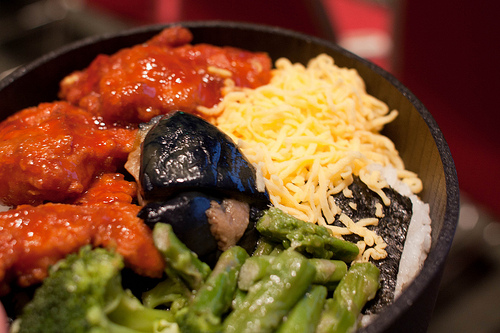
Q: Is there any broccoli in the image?
A: Yes, there is broccoli.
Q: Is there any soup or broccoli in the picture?
A: Yes, there is broccoli.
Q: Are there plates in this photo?
A: No, there are no plates.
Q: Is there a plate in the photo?
A: No, there are no plates.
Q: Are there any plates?
A: No, there are no plates.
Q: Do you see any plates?
A: No, there are no plates.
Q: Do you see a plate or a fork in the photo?
A: No, there are no plates or forks.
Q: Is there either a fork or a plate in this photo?
A: No, there are no plates or forks.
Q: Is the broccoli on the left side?
A: Yes, the broccoli is on the left of the image.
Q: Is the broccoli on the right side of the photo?
A: No, the broccoli is on the left of the image.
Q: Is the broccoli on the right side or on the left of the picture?
A: The broccoli is on the left of the image.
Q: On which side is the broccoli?
A: The broccoli is on the left of the image.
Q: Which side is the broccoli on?
A: The broccoli is on the left of the image.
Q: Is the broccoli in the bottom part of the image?
A: Yes, the broccoli is in the bottom of the image.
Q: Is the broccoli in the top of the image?
A: No, the broccoli is in the bottom of the image.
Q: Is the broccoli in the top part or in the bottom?
A: The broccoli is in the bottom of the image.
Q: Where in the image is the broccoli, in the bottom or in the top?
A: The broccoli is in the bottom of the image.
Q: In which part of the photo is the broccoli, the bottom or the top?
A: The broccoli is in the bottom of the image.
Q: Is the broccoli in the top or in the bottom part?
A: The broccoli is in the bottom of the image.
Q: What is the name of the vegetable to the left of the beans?
A: The vegetable is broccoli.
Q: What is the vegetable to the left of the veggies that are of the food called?
A: The vegetable is broccoli.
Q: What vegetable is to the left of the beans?
A: The vegetable is broccoli.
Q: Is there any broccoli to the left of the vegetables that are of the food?
A: Yes, there is broccoli to the left of the beans.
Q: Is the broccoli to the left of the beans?
A: Yes, the broccoli is to the left of the beans.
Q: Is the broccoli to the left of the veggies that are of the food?
A: Yes, the broccoli is to the left of the beans.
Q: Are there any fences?
A: No, there are no fences.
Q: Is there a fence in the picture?
A: No, there are no fences.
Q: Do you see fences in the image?
A: No, there are no fences.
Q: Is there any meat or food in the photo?
A: Yes, there is food.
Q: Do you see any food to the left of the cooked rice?
A: Yes, there is food to the left of the rice.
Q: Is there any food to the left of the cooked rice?
A: Yes, there is food to the left of the rice.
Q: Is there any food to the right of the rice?
A: No, the food is to the left of the rice.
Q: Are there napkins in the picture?
A: No, there are no napkins.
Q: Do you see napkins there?
A: No, there are no napkins.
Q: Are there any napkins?
A: No, there are no napkins.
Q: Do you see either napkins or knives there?
A: No, there are no napkins or knives.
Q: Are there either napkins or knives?
A: No, there are no napkins or knives.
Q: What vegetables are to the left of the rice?
A: The vegetables are beans.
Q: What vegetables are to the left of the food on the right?
A: The vegetables are beans.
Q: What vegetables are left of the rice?
A: The vegetables are beans.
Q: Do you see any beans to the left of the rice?
A: Yes, there are beans to the left of the rice.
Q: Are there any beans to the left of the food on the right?
A: Yes, there are beans to the left of the rice.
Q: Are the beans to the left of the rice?
A: Yes, the beans are to the left of the rice.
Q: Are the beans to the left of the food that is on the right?
A: Yes, the beans are to the left of the rice.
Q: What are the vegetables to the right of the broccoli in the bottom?
A: The vegetables are beans.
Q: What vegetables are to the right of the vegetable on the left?
A: The vegetables are beans.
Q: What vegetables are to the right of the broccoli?
A: The vegetables are beans.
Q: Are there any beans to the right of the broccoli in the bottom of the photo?
A: Yes, there are beans to the right of the broccoli.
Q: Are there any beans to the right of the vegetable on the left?
A: Yes, there are beans to the right of the broccoli.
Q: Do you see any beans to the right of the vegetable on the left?
A: Yes, there are beans to the right of the broccoli.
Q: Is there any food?
A: Yes, there is food.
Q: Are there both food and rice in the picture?
A: Yes, there are both food and rice.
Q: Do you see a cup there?
A: No, there are no cups.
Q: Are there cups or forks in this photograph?
A: No, there are no cups or forks.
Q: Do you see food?
A: Yes, there is food.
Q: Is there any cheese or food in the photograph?
A: Yes, there is food.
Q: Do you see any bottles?
A: No, there are no bottles.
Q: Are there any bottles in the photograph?
A: No, there are no bottles.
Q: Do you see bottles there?
A: No, there are no bottles.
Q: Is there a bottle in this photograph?
A: No, there are no bottles.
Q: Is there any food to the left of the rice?
A: Yes, there is food to the left of the rice.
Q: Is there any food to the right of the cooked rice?
A: No, the food is to the left of the rice.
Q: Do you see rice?
A: Yes, there is rice.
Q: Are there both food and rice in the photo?
A: Yes, there are both rice and food.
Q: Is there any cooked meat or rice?
A: Yes, there is cooked rice.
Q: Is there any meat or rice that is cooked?
A: Yes, the rice is cooked.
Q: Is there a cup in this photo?
A: No, there are no cups.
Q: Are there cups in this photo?
A: No, there are no cups.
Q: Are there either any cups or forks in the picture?
A: No, there are no cups or forks.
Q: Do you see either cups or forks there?
A: No, there are no cups or forks.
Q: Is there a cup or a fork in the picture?
A: No, there are no cups or forks.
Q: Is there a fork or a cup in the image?
A: No, there are no cups or forks.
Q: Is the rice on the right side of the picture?
A: Yes, the rice is on the right of the image.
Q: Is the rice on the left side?
A: No, the rice is on the right of the image.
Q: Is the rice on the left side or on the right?
A: The rice is on the right of the image.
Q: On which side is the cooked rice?
A: The rice is on the right of the image.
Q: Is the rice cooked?
A: Yes, the rice is cooked.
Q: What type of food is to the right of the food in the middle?
A: The food is rice.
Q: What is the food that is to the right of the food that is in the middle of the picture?
A: The food is rice.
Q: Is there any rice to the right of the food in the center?
A: Yes, there is rice to the right of the food.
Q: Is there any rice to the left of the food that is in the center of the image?
A: No, the rice is to the right of the food.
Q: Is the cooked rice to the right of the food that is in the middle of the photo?
A: Yes, the rice is to the right of the food.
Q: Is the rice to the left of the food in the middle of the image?
A: No, the rice is to the right of the food.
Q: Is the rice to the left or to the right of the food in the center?
A: The rice is to the right of the food.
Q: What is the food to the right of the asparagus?
A: The food is rice.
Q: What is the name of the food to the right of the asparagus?
A: The food is rice.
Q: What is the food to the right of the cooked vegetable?
A: The food is rice.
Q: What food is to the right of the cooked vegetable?
A: The food is rice.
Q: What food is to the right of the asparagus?
A: The food is rice.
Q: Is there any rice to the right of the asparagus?
A: Yes, there is rice to the right of the asparagus.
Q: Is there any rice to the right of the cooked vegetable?
A: Yes, there is rice to the right of the asparagus.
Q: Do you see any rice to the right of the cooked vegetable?
A: Yes, there is rice to the right of the asparagus.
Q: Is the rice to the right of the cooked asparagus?
A: Yes, the rice is to the right of the asparagus.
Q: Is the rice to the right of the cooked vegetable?
A: Yes, the rice is to the right of the asparagus.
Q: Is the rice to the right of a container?
A: No, the rice is to the right of the asparagus.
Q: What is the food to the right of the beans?
A: The food is rice.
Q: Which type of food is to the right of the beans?
A: The food is rice.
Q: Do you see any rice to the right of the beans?
A: Yes, there is rice to the right of the beans.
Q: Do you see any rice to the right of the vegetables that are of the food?
A: Yes, there is rice to the right of the beans.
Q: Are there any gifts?
A: No, there are no gifts.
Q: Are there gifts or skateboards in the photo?
A: No, there are no gifts or skateboards.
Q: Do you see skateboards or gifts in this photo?
A: No, there are no gifts or skateboards.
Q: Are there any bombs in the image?
A: No, there are no bombs.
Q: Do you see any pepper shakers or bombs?
A: No, there are no bombs or pepper shakers.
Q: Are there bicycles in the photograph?
A: No, there are no bicycles.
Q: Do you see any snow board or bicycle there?
A: No, there are no bicycles or snowboards.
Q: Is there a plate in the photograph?
A: No, there are no plates.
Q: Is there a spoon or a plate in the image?
A: No, there are no plates or spoons.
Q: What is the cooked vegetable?
A: The vegetable is an asparagus.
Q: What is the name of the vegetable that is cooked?
A: The vegetable is an asparagus.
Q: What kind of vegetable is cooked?
A: The vegetable is an asparagus.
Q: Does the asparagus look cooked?
A: Yes, the asparagus is cooked.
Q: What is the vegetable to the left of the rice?
A: The vegetable is an asparagus.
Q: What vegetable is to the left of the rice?
A: The vegetable is an asparagus.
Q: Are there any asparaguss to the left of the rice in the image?
A: Yes, there is an asparagus to the left of the rice.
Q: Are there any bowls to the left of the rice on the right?
A: No, there is an asparagus to the left of the rice.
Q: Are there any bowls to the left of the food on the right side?
A: No, there is an asparagus to the left of the rice.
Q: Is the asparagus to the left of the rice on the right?
A: Yes, the asparagus is to the left of the rice.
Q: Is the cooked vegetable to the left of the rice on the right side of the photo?
A: Yes, the asparagus is to the left of the rice.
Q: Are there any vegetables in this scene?
A: Yes, there are vegetables.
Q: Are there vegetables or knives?
A: Yes, there are vegetables.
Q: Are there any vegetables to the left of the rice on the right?
A: Yes, there are vegetables to the left of the rice.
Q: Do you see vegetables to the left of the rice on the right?
A: Yes, there are vegetables to the left of the rice.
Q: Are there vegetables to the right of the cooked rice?
A: No, the vegetables are to the left of the rice.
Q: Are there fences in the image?
A: No, there are no fences.